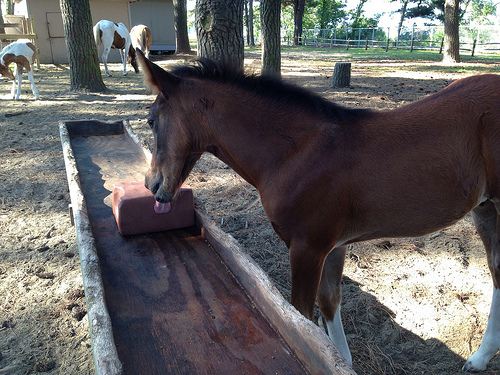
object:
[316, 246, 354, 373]
leg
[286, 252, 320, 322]
leg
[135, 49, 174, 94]
ear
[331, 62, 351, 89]
tree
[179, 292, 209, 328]
wood part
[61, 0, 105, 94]
tree trunk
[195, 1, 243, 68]
tree trunk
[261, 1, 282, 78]
tree trunk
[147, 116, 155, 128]
horse eye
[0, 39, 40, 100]
brown/white horse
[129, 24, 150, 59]
brown/white horse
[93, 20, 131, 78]
brown/white horse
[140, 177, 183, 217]
horse lick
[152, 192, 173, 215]
horse's tongue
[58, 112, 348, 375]
trough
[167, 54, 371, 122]
horse mane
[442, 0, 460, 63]
trees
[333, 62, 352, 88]
tree stump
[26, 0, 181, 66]
building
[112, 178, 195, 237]
block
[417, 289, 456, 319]
dirt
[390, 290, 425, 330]
ground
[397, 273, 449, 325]
sunlight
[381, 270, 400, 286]
dirt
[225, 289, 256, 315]
water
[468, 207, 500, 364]
legs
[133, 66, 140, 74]
eating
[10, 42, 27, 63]
spots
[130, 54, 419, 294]
horse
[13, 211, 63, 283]
field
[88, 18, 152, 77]
horse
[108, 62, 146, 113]
grass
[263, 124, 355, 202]
fur